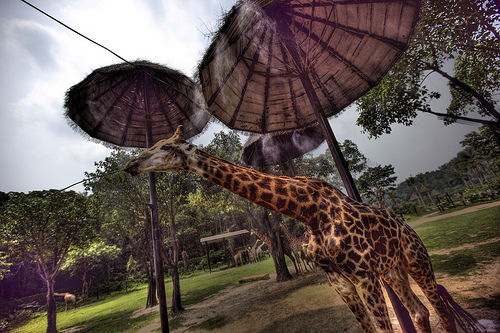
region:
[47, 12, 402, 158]
umbrellas made of natural fibers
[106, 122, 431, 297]
giraffe leaning over to side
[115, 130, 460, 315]
giraffe standing in shade and sunlight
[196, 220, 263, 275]
animals near an open building with a roof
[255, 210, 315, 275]
animals clustered by tree trunk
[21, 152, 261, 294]
dense trees at edge of grass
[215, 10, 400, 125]
inner and outer ribs supporting umbrella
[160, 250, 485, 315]
dirt paths through the grass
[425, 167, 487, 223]
structures in the distance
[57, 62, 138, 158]
fringe around edge of umbrella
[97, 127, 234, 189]
Giraffe head that is orange and brown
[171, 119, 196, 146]
Orange and brown giraffe ear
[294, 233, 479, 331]
Orange and brown giraffe legs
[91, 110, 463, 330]
Orange and brown giraffe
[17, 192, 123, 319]
Green and brown tree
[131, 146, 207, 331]
Pole attached to an umbrella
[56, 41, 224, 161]
Brown umbrella on a pole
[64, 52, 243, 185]
Wicker brown umbrella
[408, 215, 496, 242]
Grass covered green and brown ground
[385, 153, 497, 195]
Group of green trees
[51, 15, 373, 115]
Three umbrellas are seen.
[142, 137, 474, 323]
Giraffe are seen.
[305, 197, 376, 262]
Spots are brown color.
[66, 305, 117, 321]
Grass are green color.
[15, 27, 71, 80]
Clouds are white color.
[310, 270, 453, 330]
Giraffe has four legs.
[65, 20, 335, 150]
Umbrella is brown color.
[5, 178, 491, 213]
trees are seen behind the giraffe.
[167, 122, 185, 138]
Two horns are in giraffe.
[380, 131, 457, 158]
Sky is blue.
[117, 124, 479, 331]
The giraffe is under an umbrella.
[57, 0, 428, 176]
Several umbrellas provide shade.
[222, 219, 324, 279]
Several giraffes are in the background.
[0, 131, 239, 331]
The enclosure has several trees.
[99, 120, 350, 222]
The giraffe stretches out its neck.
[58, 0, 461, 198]
The umbrellas are made of wood and fabric.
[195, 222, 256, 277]
A canopy is in the background.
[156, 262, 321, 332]
There are bare patches on the ground.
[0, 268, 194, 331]
There is grass on the ground.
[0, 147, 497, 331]
The giraffes are on a hill.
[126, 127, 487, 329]
the giraffe is under the umbrellas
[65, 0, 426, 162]
the umbrellas are brown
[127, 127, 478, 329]
the giraffe is orange and brown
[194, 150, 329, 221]
the giraffe has a long neck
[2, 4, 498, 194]
the sky is cloudy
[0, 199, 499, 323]
the grass is green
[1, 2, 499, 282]
the trees have leaves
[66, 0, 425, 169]
three umbrellas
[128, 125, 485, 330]
one animal stands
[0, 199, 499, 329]
the ground has dirt